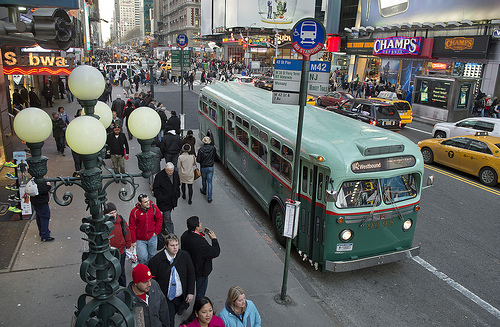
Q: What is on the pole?
A: Lights.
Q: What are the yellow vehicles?
A: Cabs.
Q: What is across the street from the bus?
A: Champs.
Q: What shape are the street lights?
A: Round.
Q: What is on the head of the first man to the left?
A: A red cap.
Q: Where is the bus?
A: At the bus stop.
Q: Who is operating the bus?
A: The driver.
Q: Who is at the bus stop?
A: Passengers.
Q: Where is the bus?
A: On the street.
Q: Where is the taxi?
A: On the street.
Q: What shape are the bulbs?
A: Spherical.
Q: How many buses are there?
A: One.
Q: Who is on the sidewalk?
A: Pedestrians.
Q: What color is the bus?
A: Green.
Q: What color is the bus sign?
A: Blue.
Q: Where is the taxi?
A: In the road.